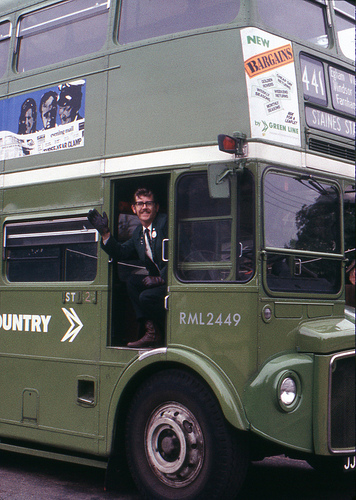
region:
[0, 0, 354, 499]
the bus is green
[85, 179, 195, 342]
the man is wearing glasses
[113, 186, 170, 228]
the man has a mustache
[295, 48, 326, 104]
the bus says 441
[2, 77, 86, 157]
the bus has an ad with three people on it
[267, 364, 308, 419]
the bus has a headlight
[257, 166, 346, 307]
the bus has a windshield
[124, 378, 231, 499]
the bus's wheel is dirty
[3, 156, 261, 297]
the bus has windows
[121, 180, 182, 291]
the man is wearing a black tie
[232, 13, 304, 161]
An advertisement on the front of the bus.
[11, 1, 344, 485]
A green double-decker bus.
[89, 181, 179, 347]
The bus driver.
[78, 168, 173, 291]
The man has black gloves on his hands.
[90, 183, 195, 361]
The man is wearing a green suit.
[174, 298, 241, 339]
The bus' number.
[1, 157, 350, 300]
The bus has a lot of windows.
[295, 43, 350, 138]
The bus' route is displayed on the front of the bus.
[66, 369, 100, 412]
A place for the driver to put his foot when he's getting on the bus.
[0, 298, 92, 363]
The name of the bus company.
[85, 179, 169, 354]
Man waving from a bus door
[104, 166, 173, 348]
Well dressed man on a bus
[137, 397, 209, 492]
Wheel well of a bus tire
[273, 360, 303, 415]
Headlight on a green bus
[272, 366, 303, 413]
Circular light on the front of the bus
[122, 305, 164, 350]
Brown boots on the man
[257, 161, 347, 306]
Windshield of the bus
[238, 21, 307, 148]
Advertisement on the front of the bus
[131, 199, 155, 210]
Glasses on the man's face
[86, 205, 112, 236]
Black glove on the man's hand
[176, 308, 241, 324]
white writing on the green bus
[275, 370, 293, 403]
a round white light on the bus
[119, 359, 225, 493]
a black and silver wheel on the bus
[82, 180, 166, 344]
a man in the bus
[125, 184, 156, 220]
the man's head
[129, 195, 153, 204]
a pair of glasses on the man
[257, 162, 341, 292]
a front window on the bus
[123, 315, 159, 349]
a brown boot on the man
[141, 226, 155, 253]
a black tie around the man's neck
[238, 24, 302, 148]
a sign on the front of the bus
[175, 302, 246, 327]
bus number on side of bus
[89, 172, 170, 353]
bus driver waving out the door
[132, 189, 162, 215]
glasses on bus drivers face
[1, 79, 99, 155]
advertising on side of bus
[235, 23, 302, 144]
advertising on front of bus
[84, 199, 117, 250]
black glove on hand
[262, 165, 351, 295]
front window of bus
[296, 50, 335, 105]
441 number of next stop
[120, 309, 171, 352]
brown boot on foot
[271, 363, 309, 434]
right headlight of bus